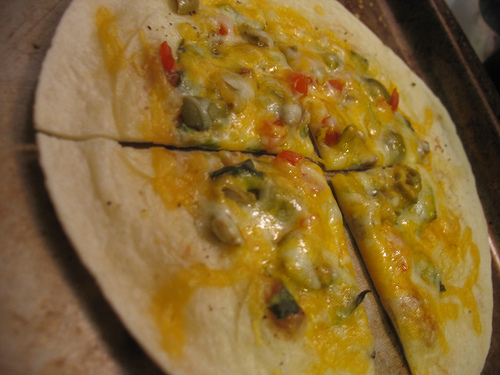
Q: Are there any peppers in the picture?
A: Yes, there are peppers.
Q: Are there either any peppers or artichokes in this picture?
A: Yes, there are peppers.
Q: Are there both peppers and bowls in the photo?
A: No, there are peppers but no bowls.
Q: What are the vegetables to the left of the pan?
A: The vegetables are peppers.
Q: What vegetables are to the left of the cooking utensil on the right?
A: The vegetables are peppers.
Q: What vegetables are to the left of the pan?
A: The vegetables are peppers.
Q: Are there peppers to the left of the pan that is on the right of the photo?
A: Yes, there are peppers to the left of the pan.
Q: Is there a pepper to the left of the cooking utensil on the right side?
A: Yes, there are peppers to the left of the pan.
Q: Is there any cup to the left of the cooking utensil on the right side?
A: No, there are peppers to the left of the pan.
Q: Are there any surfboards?
A: No, there are no surfboards.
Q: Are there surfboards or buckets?
A: No, there are no surfboards or buckets.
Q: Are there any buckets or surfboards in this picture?
A: No, there are no surfboards or buckets.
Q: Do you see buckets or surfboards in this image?
A: No, there are no surfboards or buckets.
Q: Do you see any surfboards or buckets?
A: No, there are no surfboards or buckets.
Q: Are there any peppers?
A: Yes, there are peppers.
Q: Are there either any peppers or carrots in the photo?
A: Yes, there are peppers.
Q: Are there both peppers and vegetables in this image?
A: Yes, there are both peppers and a vegetable.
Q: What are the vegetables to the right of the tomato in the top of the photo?
A: The vegetables are peppers.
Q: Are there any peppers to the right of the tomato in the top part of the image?
A: Yes, there are peppers to the right of the tomato.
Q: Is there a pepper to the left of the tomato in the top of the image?
A: No, the peppers are to the right of the tomato.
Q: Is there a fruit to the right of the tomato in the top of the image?
A: No, there are peppers to the right of the tomato.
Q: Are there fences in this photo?
A: No, there are no fences.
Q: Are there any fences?
A: No, there are no fences.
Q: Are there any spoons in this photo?
A: No, there are no spoons.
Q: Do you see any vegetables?
A: Yes, there are vegetables.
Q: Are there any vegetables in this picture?
A: Yes, there are vegetables.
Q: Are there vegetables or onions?
A: Yes, there are vegetables.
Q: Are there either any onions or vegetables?
A: Yes, there are vegetables.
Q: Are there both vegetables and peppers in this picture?
A: Yes, there are both vegetables and peppers.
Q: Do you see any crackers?
A: No, there are no crackers.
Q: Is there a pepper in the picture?
A: Yes, there is a pepper.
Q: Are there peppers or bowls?
A: Yes, there is a pepper.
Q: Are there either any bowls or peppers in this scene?
A: Yes, there is a pepper.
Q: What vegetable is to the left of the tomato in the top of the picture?
A: The vegetable is a pepper.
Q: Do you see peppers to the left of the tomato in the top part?
A: Yes, there is a pepper to the left of the tomato.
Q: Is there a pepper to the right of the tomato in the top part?
A: No, the pepper is to the left of the tomato.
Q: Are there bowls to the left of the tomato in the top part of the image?
A: No, there is a pepper to the left of the tomato.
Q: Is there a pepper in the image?
A: Yes, there is a pepper.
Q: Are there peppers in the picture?
A: Yes, there is a pepper.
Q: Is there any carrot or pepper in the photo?
A: Yes, there is a pepper.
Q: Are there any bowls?
A: No, there are no bowls.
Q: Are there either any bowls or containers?
A: No, there are no bowls or containers.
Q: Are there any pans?
A: Yes, there is a pan.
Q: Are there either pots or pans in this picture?
A: Yes, there is a pan.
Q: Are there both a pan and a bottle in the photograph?
A: No, there is a pan but no bottles.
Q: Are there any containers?
A: No, there are no containers.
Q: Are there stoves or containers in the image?
A: No, there are no containers or stoves.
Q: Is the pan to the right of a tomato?
A: Yes, the pan is to the right of a tomato.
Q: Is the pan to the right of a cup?
A: No, the pan is to the right of a tomato.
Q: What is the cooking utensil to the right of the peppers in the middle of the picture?
A: The cooking utensil is a pan.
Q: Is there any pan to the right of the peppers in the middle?
A: Yes, there is a pan to the right of the peppers.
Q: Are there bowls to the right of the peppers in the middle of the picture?
A: No, there is a pan to the right of the peppers.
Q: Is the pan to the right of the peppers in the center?
A: Yes, the pan is to the right of the peppers.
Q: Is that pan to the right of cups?
A: No, the pan is to the right of the peppers.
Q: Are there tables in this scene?
A: Yes, there is a table.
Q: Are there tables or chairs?
A: Yes, there is a table.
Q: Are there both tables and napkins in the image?
A: No, there is a table but no napkins.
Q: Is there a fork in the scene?
A: No, there are no forks.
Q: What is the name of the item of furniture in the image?
A: The piece of furniture is a table.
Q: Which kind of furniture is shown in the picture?
A: The furniture is a table.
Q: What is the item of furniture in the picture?
A: The piece of furniture is a table.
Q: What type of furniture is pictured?
A: The furniture is a table.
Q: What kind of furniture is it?
A: The piece of furniture is a table.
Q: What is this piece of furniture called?
A: This is a table.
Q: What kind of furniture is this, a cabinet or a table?
A: This is a table.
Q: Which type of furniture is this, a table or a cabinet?
A: This is a table.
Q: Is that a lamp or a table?
A: That is a table.